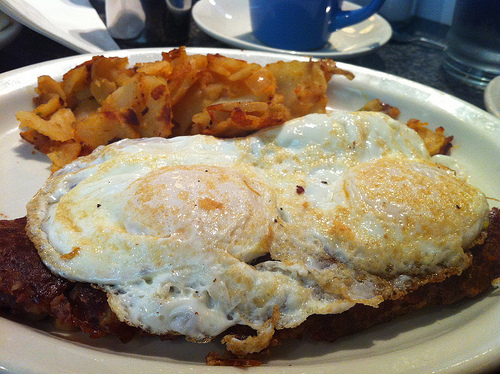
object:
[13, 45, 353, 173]
potatoes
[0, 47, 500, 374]
plate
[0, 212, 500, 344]
meat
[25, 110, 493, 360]
egg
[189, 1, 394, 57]
saucer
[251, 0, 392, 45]
mug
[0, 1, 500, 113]
table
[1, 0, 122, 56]
napkin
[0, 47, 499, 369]
breakfast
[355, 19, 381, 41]
light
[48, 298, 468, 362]
shadow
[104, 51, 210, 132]
bunch